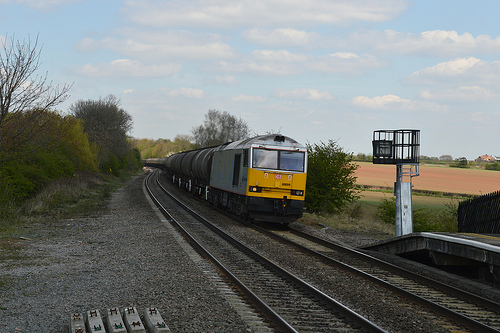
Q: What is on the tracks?
A: Train.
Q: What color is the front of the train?
A: Yellow.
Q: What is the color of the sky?
A: Blue.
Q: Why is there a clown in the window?
A: There is no clown.